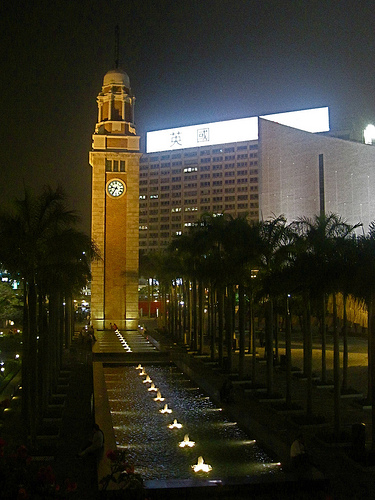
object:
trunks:
[282, 298, 294, 416]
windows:
[106, 159, 126, 175]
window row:
[195, 151, 260, 164]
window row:
[195, 143, 259, 155]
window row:
[136, 160, 257, 179]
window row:
[137, 166, 258, 186]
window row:
[138, 175, 183, 187]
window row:
[201, 193, 258, 204]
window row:
[250, 216, 259, 223]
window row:
[136, 198, 199, 209]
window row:
[200, 201, 258, 211]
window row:
[183, 218, 258, 229]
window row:
[199, 169, 235, 180]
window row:
[140, 237, 171, 246]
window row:
[140, 238, 168, 245]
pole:
[109, 24, 123, 69]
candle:
[142, 376, 154, 385]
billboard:
[138, 103, 333, 156]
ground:
[0, 303, 375, 440]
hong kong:
[1, 2, 371, 495]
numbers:
[120, 187, 123, 190]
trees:
[323, 218, 344, 463]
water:
[130, 382, 153, 447]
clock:
[107, 179, 124, 197]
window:
[156, 195, 158, 198]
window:
[195, 167, 198, 173]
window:
[178, 207, 181, 213]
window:
[143, 194, 146, 200]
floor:
[63, 328, 291, 419]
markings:
[109, 189, 112, 193]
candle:
[191, 454, 214, 475]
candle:
[159, 403, 172, 414]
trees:
[339, 211, 355, 388]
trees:
[0, 175, 40, 432]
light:
[135, 363, 144, 370]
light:
[138, 368, 148, 376]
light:
[153, 389, 167, 402]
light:
[167, 417, 183, 430]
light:
[176, 431, 198, 448]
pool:
[89, 358, 298, 500]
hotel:
[139, 139, 257, 265]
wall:
[263, 145, 372, 233]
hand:
[111, 186, 117, 195]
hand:
[110, 184, 116, 189]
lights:
[184, 168, 187, 172]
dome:
[89, 64, 141, 152]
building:
[85, 23, 144, 331]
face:
[107, 179, 124, 197]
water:
[136, 416, 249, 468]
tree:
[39, 177, 47, 415]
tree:
[65, 236, 107, 345]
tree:
[0, 191, 34, 459]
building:
[130, 105, 375, 331]